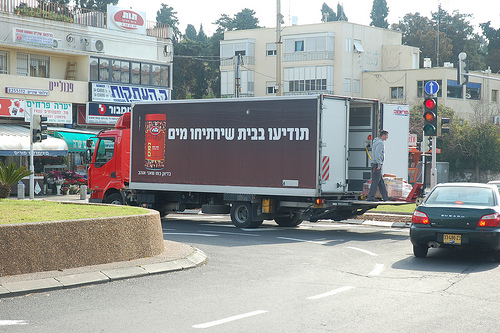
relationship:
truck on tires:
[61, 76, 385, 269] [218, 186, 283, 243]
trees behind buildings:
[414, 15, 477, 60] [214, 17, 471, 172]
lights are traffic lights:
[423, 96, 440, 135] [408, 94, 441, 162]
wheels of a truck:
[88, 184, 141, 204] [72, 101, 358, 243]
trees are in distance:
[191, 50, 201, 55] [4, 99, 496, 113]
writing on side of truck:
[164, 125, 309, 142] [85, 100, 405, 231]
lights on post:
[423, 96, 440, 135] [422, 137, 435, 194]